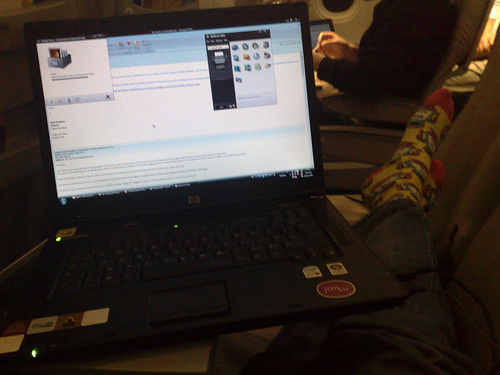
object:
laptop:
[8, 0, 409, 373]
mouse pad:
[148, 278, 232, 327]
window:
[321, 0, 352, 15]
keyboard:
[54, 205, 339, 297]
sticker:
[302, 262, 357, 299]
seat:
[205, 22, 500, 375]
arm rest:
[318, 125, 405, 165]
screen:
[35, 21, 315, 200]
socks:
[359, 87, 454, 212]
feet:
[360, 87, 455, 213]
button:
[56, 205, 337, 295]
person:
[311, 0, 462, 102]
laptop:
[304, 17, 337, 50]